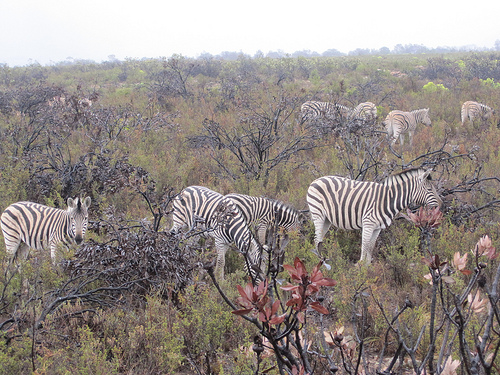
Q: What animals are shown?
A: Zebras.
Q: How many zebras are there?
A: Eight.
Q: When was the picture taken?
A: Day time.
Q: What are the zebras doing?
A: Grazing.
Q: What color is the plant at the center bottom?
A: Brown.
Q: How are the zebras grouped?
A: Four in the foreground, four in the background.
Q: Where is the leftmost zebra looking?
A: Toward the camera.